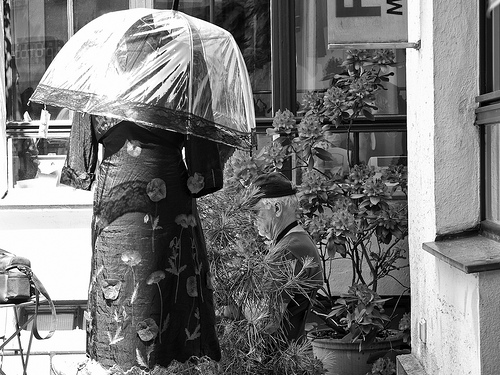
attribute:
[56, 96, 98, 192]
sleeve — on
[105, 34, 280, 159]
umbrella — clear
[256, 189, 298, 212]
hair — on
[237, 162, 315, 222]
hat — on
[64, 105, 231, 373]
floral dress — dark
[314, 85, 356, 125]
flower — in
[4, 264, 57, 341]
purse — on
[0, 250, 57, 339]
camera bag — on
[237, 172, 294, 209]
cap — black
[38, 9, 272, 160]
umbrella — clear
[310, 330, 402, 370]
pot — on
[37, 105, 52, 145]
tag — on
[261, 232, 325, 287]
shirt — on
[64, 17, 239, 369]
person — holding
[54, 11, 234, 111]
canopy — clear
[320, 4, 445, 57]
sign — advertising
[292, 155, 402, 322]
plant — in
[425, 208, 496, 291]
ledge — on